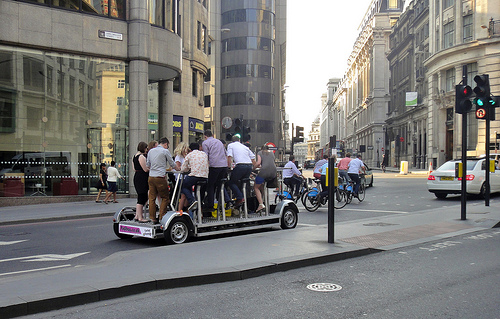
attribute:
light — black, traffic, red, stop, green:
[474, 96, 485, 120]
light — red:
[455, 82, 478, 123]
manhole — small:
[305, 276, 338, 302]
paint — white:
[18, 242, 108, 262]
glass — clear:
[62, 88, 102, 125]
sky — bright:
[315, 16, 347, 39]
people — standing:
[119, 120, 277, 157]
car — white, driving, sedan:
[429, 154, 495, 194]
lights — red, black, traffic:
[437, 65, 500, 143]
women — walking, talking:
[95, 145, 120, 226]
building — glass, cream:
[324, 75, 386, 141]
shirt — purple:
[216, 160, 224, 164]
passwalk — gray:
[109, 243, 221, 294]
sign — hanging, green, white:
[408, 99, 419, 129]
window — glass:
[229, 41, 276, 67]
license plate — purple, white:
[105, 219, 168, 245]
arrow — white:
[5, 233, 44, 258]